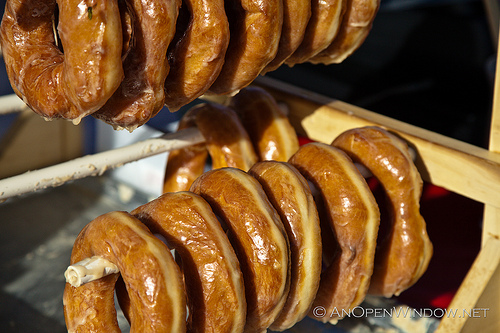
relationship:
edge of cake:
[360, 162, 386, 187] [332, 125, 435, 298]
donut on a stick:
[63, 211, 188, 331] [52, 144, 145, 170]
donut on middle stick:
[162, 100, 258, 193] [0, 100, 289, 202]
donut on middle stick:
[228, 84, 300, 165] [0, 100, 289, 202]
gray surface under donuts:
[0, 169, 410, 329] [21, 18, 438, 331]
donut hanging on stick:
[164, 104, 258, 194] [67, 256, 102, 284]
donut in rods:
[1, 0, 124, 126] [44, 159, 106, 180]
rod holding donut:
[2, 102, 290, 207] [159, 100, 259, 202]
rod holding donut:
[2, 102, 290, 207] [228, 84, 300, 165]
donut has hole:
[58, 217, 181, 330] [97, 261, 134, 325]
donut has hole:
[1, 2, 113, 119] [34, 7, 63, 66]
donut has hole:
[164, 104, 258, 194] [197, 147, 219, 186]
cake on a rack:
[332, 125, 435, 298] [0, 2, 497, 330]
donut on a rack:
[250, 152, 320, 331] [52, 132, 435, 329]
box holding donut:
[255, 77, 498, 284] [150, 209, 286, 297]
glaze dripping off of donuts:
[69, 108, 115, 124] [143, 112, 476, 332]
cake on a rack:
[332, 125, 435, 298] [61, 239, 121, 300]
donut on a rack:
[63, 211, 188, 331] [58, 246, 121, 290]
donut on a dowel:
[164, 104, 258, 194] [2, 125, 203, 187]